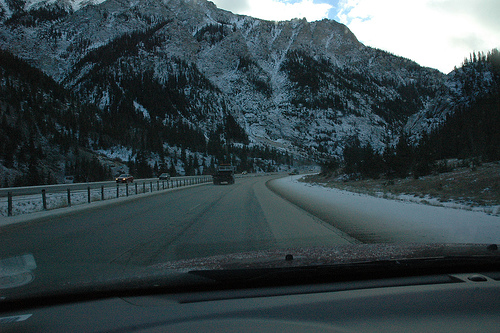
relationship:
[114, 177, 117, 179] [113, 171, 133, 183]
headlight on car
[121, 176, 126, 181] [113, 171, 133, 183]
headlight on car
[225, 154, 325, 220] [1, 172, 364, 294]
curve to right road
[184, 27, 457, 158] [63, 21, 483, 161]
snow covered mountains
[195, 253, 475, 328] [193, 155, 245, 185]
hood of car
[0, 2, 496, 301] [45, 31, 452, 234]
car windshield in car windshield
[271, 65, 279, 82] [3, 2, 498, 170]
snow on mountain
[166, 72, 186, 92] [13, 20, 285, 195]
tree on hill top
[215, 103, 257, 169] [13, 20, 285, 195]
tree on hill top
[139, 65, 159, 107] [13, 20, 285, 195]
tree on hill top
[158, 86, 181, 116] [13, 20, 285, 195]
tree on hill top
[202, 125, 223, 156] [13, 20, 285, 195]
tree on hill top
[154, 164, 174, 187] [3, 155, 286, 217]
car on road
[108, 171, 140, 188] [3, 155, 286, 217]
car on road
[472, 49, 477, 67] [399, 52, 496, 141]
tree on mountainside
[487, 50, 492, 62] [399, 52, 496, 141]
tree on mountainside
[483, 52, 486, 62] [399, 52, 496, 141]
tree on mountainside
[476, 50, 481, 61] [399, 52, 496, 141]
tree on mountainside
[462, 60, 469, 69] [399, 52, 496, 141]
tree on mountainside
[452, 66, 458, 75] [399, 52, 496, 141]
tree on mountainside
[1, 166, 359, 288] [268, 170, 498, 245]
road with snow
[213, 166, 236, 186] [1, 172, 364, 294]
car traveling on road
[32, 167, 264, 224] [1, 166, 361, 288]
fence on road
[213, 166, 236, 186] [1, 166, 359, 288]
car on road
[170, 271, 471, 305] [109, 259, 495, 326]
vent on dashboard